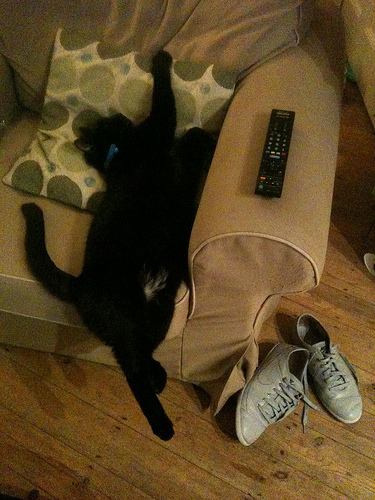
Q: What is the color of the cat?
A: Black.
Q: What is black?
A: Cat.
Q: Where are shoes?
A: On the floor.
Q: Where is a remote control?
A: On the couch.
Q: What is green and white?
A: Pillow.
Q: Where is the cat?
A: On the couch.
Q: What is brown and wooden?
A: The floor.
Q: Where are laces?
A: On the shoes.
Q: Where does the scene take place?
A: In a living room.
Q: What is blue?
A: Cat's collar.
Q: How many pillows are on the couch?
A: One.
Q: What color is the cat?
A: Black.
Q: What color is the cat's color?
A: Blue.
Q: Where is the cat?
A: On a sofa.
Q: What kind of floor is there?
A: Wooden.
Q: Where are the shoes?
A: On the floor.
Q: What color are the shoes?
A: Grey.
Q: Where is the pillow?
A: On the sofa.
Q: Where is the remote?
A: On the arm of the sofa.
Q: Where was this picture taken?
A: In a house.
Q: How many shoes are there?
A: 2.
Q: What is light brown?
A: Couch.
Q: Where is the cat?
A: On a couch.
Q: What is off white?
A: Shoes.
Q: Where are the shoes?
A: On the floor.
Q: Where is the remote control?
A: On the couch.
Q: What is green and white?
A: Pillow.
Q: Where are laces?
A: On the shoes.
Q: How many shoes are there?
A: Two.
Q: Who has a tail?
A: The cat.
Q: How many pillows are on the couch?
A: One.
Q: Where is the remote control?
A: On the chair's arm.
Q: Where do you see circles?
A: On the pillow.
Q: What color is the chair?
A: Brown.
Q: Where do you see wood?
A: On the floor.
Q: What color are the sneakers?
A: Gray.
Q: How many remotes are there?
A: One.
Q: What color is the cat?
A: Black.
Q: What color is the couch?
A: Tan.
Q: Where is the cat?
A: The couch.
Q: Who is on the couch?
A: A cat.